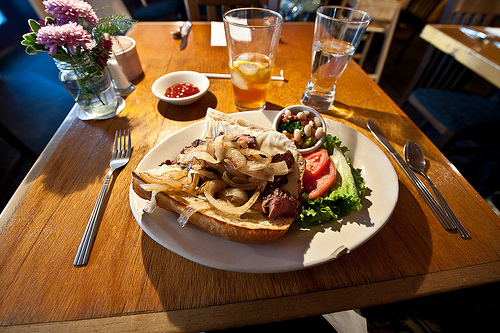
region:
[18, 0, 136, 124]
Flowers in a vase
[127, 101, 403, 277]
Food on a plate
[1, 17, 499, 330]
A brown wooden table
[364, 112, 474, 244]
A silver spoon and knife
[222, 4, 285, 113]
Beverage and ice in a glass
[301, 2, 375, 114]
A glass of water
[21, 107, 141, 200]
Shadow on the table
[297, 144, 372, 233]
Tomatoes on green lettuce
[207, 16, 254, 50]
The napkin is white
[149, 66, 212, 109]
Ketchup in a small bowl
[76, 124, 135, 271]
a fork is on the table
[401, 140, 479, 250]
a spoon is on the table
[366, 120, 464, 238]
a knife is on the table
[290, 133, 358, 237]
a piece of lettuce on the plate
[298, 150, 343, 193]
tomatoes on the plate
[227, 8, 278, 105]
a glass of tea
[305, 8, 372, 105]
a clear glass with water in it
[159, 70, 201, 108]
ketchup in a little white bowl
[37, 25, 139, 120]
flowers in water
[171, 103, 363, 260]
a sandwich on a plate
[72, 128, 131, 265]
the fork on the table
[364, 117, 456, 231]
the butterknife on the table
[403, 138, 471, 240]
the spoon on the table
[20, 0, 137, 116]
the flowers in the jar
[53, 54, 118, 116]
the clear jar holding the flowers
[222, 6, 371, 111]
the two clear glass cups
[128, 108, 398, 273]
the white plate on the table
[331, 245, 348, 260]
the chip on the plate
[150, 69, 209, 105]
the small bowl on the table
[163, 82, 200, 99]
the ketchup in the bowl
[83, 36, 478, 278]
a plate of food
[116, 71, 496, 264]
a white plate of food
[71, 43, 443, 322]
food on a plate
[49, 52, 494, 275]
foodon a white plate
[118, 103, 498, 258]
a sandwich on a plate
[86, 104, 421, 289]
a plate with a sandwich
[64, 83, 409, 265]
lettuce on a plate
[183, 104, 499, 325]
tomato slices on a plate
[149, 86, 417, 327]
tomatos on a plate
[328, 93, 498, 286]
silverware on a table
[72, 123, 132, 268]
A silver long salad fork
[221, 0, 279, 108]
a half full glass of iced tea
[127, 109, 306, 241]
An open faced sandwich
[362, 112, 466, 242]
The spoon and knife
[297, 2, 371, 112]
A half full glass of water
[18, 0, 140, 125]
Purple flowers in a vase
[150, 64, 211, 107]
A side bowl of catsup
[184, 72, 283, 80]
A straw still in the wrapper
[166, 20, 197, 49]
A spoon and knife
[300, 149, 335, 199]
two tomatoes